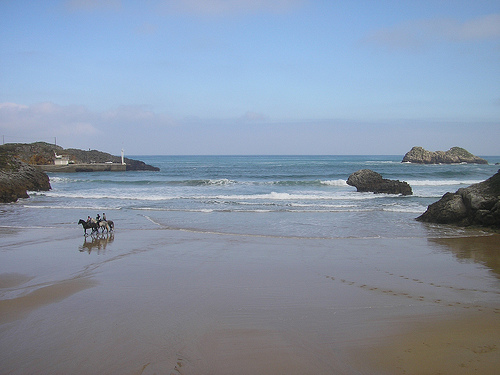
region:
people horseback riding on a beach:
[60, 206, 118, 248]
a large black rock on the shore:
[346, 161, 412, 208]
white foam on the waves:
[215, 192, 262, 199]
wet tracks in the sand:
[363, 272, 417, 300]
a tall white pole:
[117, 146, 131, 171]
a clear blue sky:
[120, 37, 179, 91]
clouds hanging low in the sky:
[46, 102, 99, 129]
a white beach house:
[54, 150, 76, 168]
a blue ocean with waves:
[224, 161, 262, 173]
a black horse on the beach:
[76, 217, 94, 232]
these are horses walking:
[74, 206, 118, 241]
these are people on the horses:
[87, 210, 107, 222]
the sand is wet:
[95, 250, 410, 374]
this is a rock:
[396, 145, 475, 167]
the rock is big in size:
[402, 143, 479, 163]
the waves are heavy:
[176, 168, 337, 193]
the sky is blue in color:
[8, 0, 494, 61]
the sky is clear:
[0, 3, 495, 88]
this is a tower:
[48, 153, 72, 169]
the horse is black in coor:
[80, 220, 95, 225]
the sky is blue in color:
[189, 36, 309, 84]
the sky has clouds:
[6, 105, 85, 140]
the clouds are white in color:
[0, 110, 87, 135]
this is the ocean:
[201, 151, 328, 166]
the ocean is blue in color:
[204, 154, 302, 176]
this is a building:
[43, 149, 135, 175]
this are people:
[69, 203, 123, 260]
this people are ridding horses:
[60, 203, 128, 243]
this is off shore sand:
[63, 203, 381, 345]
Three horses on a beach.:
[76, 215, 116, 240]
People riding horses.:
[76, 210, 116, 241]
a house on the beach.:
[53, 151, 70, 166]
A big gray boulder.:
[345, 167, 412, 196]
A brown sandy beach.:
[1, 205, 497, 372]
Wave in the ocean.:
[19, 175, 487, 215]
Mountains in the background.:
[1, 140, 161, 205]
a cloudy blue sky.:
[3, 2, 498, 157]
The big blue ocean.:
[9, 153, 499, 214]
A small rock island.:
[401, 145, 489, 165]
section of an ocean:
[226, 162, 266, 172]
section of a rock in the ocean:
[413, 154, 443, 159]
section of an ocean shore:
[238, 296, 329, 316]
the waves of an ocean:
[204, 178, 225, 186]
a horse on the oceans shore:
[83, 225, 93, 231]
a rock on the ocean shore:
[465, 196, 489, 219]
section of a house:
[58, 155, 62, 162]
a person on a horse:
[102, 214, 104, 221]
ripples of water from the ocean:
[238, 202, 315, 218]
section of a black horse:
[84, 224, 89, 234]